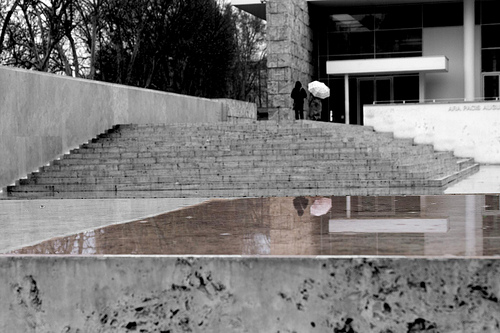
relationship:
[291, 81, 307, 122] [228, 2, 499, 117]
person near building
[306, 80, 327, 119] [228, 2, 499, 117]
person near building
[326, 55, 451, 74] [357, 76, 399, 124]
awning over door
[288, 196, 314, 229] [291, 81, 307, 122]
reflection of person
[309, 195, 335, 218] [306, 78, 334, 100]
reflection of umbrella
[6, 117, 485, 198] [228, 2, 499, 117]
steps to building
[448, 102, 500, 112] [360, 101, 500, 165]
name on wall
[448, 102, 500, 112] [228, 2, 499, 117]
name of building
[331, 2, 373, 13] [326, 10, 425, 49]
lights on ceiling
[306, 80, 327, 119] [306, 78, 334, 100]
woman holding umbrella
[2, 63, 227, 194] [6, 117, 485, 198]
wall across steps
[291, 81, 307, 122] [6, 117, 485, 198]
person above steps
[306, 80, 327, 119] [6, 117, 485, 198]
person above steps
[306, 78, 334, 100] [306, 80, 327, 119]
umbrella over person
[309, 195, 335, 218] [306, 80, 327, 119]
reflection of person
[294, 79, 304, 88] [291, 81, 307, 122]
head of woman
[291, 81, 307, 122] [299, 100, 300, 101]
woman wearing black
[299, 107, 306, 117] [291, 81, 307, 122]
leg of person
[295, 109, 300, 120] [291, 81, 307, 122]
leg of person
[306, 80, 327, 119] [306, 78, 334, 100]
person carrying umbrella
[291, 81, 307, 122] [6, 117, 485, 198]
person above stairs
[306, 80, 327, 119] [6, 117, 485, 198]
person above stairs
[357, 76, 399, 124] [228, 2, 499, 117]
entrance to building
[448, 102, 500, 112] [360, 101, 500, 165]
writing on wall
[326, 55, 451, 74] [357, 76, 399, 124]
over hang to entrance